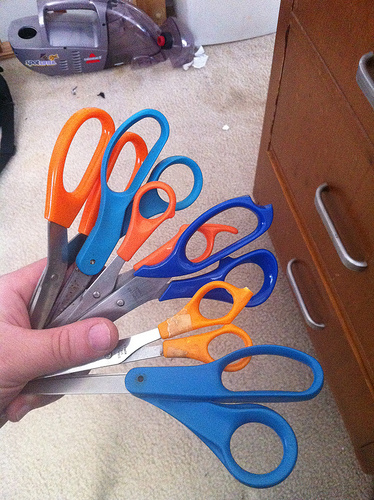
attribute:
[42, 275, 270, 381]
scissors — orange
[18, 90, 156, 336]
scissors — orange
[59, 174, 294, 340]
scissors — blue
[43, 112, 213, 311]
scissors — blue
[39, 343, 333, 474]
scissors — blue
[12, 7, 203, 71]
carpet shampooer — handheld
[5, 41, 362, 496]
floor — white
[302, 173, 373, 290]
handle — silver, metal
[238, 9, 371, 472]
dresser — brown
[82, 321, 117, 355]
thumbnail — short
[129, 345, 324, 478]
handle — blue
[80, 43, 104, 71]
logo — red